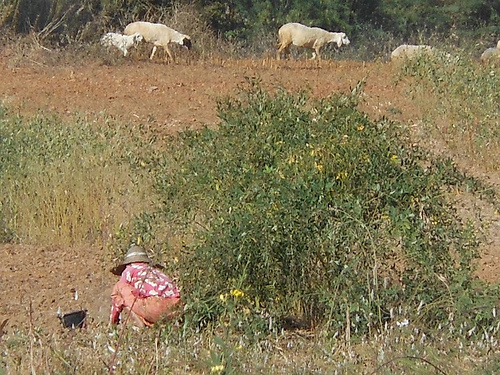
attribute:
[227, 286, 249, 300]
flower — yellow, little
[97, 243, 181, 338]
woman — bending down, crouching, kneeling, working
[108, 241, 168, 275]
hat — green, brown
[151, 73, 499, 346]
bush — green, dead, big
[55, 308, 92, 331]
bucket — black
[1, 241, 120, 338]
grass — dead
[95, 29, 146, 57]
sheep — white, baby, walking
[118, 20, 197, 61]
sheep — white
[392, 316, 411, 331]
flower — white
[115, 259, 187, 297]
scarf — red, white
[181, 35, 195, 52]
face — black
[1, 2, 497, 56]
trees — in background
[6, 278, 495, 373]
grass — dried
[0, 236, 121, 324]
dirt patch — big